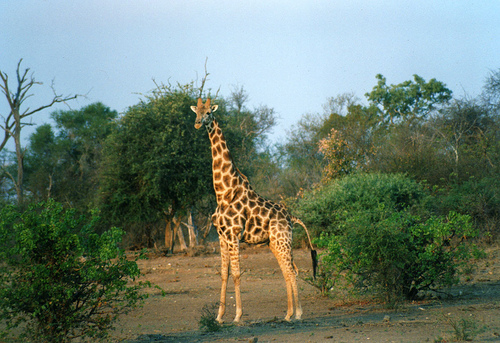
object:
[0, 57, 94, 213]
tree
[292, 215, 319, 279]
tail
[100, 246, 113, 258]
leaves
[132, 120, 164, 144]
leaves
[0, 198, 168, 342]
bush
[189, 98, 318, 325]
giraffe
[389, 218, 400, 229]
leafs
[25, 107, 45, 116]
branches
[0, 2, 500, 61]
sky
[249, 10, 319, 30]
clouds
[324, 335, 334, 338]
rocks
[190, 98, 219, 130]
head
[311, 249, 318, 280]
hair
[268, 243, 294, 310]
legs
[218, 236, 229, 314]
legs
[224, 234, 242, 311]
legs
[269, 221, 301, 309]
legs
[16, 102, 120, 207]
trees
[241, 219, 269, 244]
belly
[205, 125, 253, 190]
neck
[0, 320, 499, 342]
dirt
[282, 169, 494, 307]
bush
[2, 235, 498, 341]
field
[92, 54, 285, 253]
tree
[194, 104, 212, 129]
face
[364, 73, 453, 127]
tree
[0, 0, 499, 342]
scene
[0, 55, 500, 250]
bushes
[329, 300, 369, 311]
badsentence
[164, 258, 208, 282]
ground